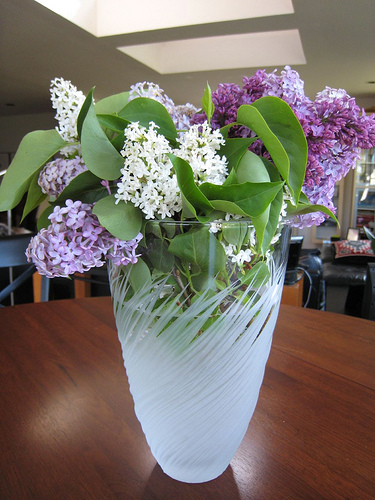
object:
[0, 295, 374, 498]
table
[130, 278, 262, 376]
grass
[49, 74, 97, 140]
flowers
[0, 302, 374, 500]
wooden top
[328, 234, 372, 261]
pillow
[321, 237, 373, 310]
couch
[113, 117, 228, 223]
flowers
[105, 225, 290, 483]
flower pot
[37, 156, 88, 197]
flowers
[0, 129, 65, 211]
leaf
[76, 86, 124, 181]
leaf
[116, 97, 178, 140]
leaf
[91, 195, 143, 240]
leaf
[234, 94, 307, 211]
leaf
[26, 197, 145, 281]
flowers